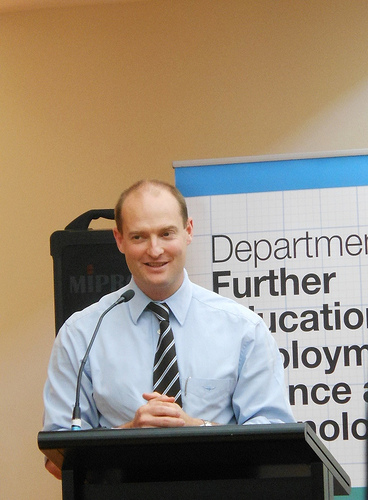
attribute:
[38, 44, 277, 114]
wall — white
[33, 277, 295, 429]
shirt — blue, button up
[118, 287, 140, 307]
microphone — foam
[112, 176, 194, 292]
head — balding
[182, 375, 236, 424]
pocket — blue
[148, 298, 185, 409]
tie — black and white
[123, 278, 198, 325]
collar — blue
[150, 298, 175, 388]
tie — black, blue, striped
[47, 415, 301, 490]
podium — large, black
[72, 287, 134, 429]
microphone — black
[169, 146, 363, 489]
sign — for seminar, blue, white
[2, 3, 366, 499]
wall — beige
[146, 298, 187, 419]
tie — striped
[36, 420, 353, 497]
podium — tall, black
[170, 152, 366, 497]
screen — blue, white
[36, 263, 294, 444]
shirt — long sleeve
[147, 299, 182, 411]
tie — blue, black, striped